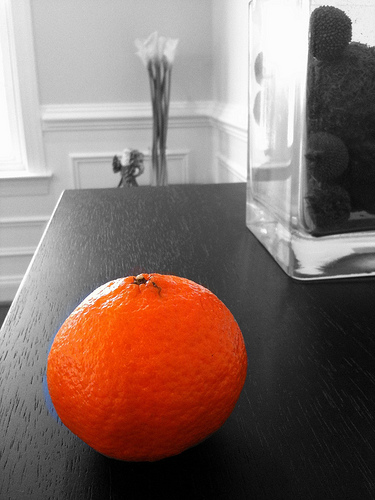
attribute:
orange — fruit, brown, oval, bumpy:
[47, 272, 246, 462]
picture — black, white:
[2, 2, 372, 497]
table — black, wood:
[2, 184, 374, 499]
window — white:
[0, 1, 53, 198]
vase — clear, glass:
[245, 2, 373, 280]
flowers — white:
[133, 29, 178, 185]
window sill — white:
[1, 169, 57, 198]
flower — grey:
[112, 148, 147, 186]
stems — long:
[145, 60, 172, 185]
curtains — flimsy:
[3, 2, 27, 169]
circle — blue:
[37, 373, 103, 457]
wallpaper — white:
[30, 0, 211, 106]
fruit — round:
[47, 272, 247, 461]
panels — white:
[1, 114, 225, 290]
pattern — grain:
[247, 305, 358, 469]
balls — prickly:
[310, 6, 372, 226]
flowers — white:
[133, 32, 182, 64]